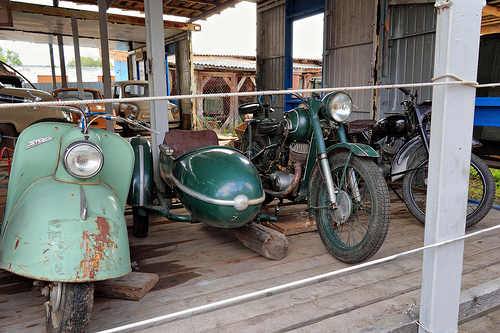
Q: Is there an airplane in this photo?
A: No, there are no airplanes.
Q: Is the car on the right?
A: No, the car is on the left of the image.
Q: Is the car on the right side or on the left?
A: The car is on the left of the image.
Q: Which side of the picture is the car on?
A: The car is on the left of the image.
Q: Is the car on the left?
A: Yes, the car is on the left of the image.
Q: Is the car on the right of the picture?
A: No, the car is on the left of the image.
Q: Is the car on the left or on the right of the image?
A: The car is on the left of the image.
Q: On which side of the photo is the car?
A: The car is on the left of the image.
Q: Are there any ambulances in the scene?
A: No, there are no ambulances.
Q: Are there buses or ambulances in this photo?
A: No, there are no ambulances or buses.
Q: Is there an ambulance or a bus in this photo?
A: No, there are no ambulances or buses.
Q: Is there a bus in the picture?
A: No, there are no buses.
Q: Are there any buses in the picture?
A: No, there are no buses.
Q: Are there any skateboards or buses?
A: No, there are no buses or skateboards.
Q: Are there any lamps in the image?
A: No, there are no lamps.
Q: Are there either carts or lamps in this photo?
A: No, there are no lamps or carts.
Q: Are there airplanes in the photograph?
A: No, there are no airplanes.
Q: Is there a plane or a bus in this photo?
A: No, there are no airplanes or buses.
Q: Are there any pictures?
A: No, there are no pictures.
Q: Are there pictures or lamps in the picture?
A: No, there are no pictures or lamps.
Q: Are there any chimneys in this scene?
A: No, there are no chimneys.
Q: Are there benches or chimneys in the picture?
A: No, there are no chimneys or benches.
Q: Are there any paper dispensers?
A: No, there are no paper dispensers.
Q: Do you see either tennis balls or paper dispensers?
A: No, there are no paper dispensers or tennis balls.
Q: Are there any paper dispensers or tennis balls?
A: No, there are no paper dispensers or tennis balls.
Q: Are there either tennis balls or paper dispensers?
A: No, there are no paper dispensers or tennis balls.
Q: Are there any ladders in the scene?
A: No, there are no ladders.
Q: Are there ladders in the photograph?
A: No, there are no ladders.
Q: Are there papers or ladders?
A: No, there are no ladders or papers.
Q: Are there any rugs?
A: No, there are no rugs.